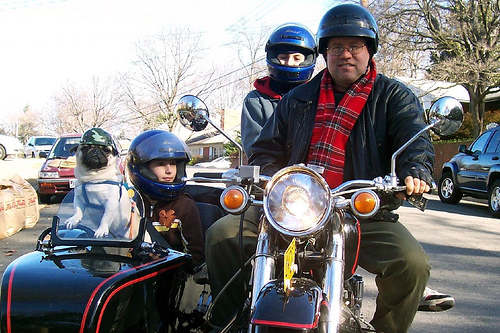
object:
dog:
[60, 121, 165, 260]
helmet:
[63, 124, 125, 153]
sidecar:
[2, 172, 230, 333]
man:
[197, 4, 441, 331]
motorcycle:
[169, 72, 467, 333]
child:
[126, 127, 211, 318]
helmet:
[127, 128, 194, 202]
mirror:
[417, 86, 472, 142]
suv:
[421, 119, 499, 224]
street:
[324, 178, 500, 333]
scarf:
[296, 59, 392, 192]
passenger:
[240, 17, 320, 168]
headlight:
[259, 161, 341, 237]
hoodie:
[250, 73, 283, 102]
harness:
[71, 178, 128, 211]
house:
[389, 68, 500, 132]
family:
[33, 3, 466, 333]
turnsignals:
[214, 181, 253, 216]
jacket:
[247, 63, 445, 221]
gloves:
[397, 164, 438, 187]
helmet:
[309, 2, 389, 57]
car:
[31, 128, 130, 207]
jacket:
[132, 186, 213, 275]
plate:
[280, 237, 301, 291]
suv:
[0, 125, 32, 164]